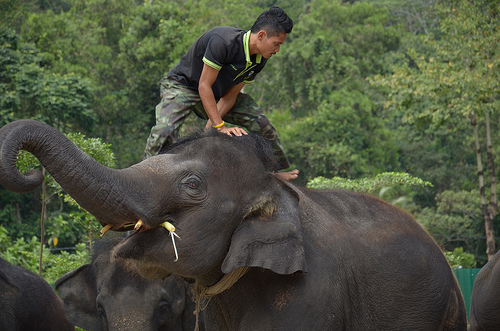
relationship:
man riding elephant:
[144, 14, 310, 171] [5, 115, 472, 330]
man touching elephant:
[144, 14, 310, 171] [5, 115, 472, 330]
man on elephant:
[144, 14, 310, 171] [5, 115, 472, 330]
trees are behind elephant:
[4, 2, 499, 199] [5, 115, 472, 330]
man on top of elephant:
[144, 14, 310, 171] [5, 115, 472, 330]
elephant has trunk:
[5, 115, 472, 330] [3, 118, 176, 236]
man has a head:
[144, 14, 310, 171] [246, 10, 309, 68]